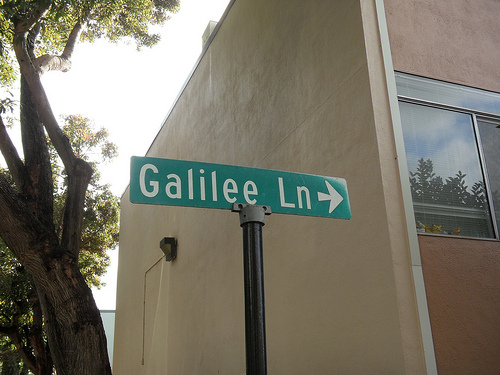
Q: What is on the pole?
A: Street sign.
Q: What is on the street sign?
A: Green and white sign.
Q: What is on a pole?
A: A sign.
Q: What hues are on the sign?
A: Green and white.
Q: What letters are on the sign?
A: Galilee ln.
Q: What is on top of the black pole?
A: A street sign.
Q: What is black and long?
A: A metal pole.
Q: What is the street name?
A: Galilee Ln.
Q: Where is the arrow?
A: On the street sign/.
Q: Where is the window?
A: On front of the building?.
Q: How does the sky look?
A: Gray.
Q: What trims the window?
A: Metal.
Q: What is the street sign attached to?
A: Metal pole.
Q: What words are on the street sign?
A: Galilee Ln.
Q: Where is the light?
A: On the side of the building.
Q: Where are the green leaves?
A: On the tree.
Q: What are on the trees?
A: Green leaves.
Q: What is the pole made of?
A: Metal.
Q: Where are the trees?
A: Next to the building.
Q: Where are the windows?
A: On the building.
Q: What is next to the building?
A: Trees.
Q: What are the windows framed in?
A: Metal.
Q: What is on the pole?
A: A sign.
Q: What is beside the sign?
A: A tree.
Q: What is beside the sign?
A: A building.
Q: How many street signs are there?
A: One.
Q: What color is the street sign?
A: Green and white.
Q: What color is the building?
A: Tan.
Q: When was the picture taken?
A: Daytime.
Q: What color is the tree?
A: Green.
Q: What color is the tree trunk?
A: Brown.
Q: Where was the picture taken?
A: On a street corner.